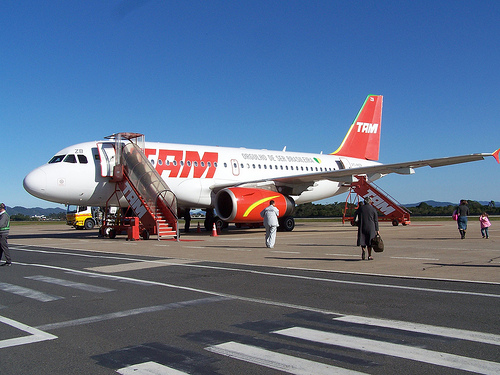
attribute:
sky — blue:
[283, 7, 315, 61]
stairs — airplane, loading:
[112, 134, 180, 238]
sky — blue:
[281, 3, 475, 92]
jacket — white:
[260, 205, 278, 228]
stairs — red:
[108, 147, 187, 239]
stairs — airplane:
[113, 152, 183, 238]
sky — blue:
[6, 5, 498, 127]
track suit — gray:
[265, 206, 273, 233]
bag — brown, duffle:
[450, 210, 461, 220]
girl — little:
[469, 199, 499, 237]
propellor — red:
[211, 182, 296, 224]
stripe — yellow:
[242, 193, 277, 215]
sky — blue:
[0, 0, 499, 212]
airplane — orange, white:
[22, 93, 498, 243]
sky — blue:
[24, 13, 482, 76]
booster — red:
[213, 183, 297, 230]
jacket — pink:
[478, 213, 490, 232]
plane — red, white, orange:
[22, 93, 499, 232]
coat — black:
[360, 204, 373, 246]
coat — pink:
[480, 215, 492, 225]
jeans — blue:
[477, 228, 493, 238]